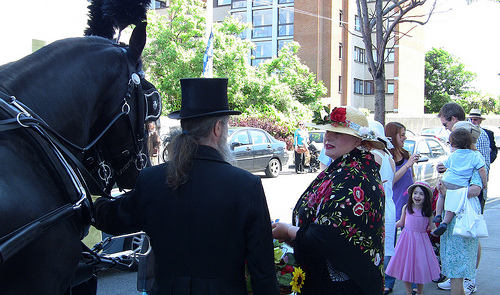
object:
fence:
[369, 113, 500, 133]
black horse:
[0, 33, 160, 283]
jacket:
[294, 146, 386, 285]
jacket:
[90, 143, 276, 293]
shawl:
[290, 147, 403, 295]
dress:
[380, 204, 442, 284]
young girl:
[382, 180, 442, 294]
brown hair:
[407, 184, 431, 215]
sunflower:
[281, 266, 307, 291]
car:
[225, 126, 289, 179]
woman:
[382, 122, 423, 252]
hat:
[166, 75, 246, 121]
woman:
[272, 103, 387, 293]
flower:
[330, 106, 351, 127]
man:
[93, 75, 274, 295]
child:
[427, 127, 489, 238]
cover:
[305, 105, 388, 150]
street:
[255, 143, 500, 218]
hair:
[163, 106, 204, 192]